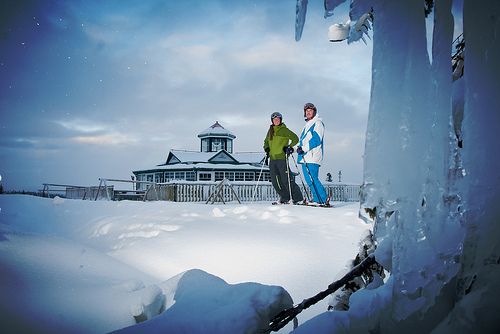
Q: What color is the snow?
A: White.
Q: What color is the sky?
A: Blue.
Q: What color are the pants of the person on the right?
A: Blue.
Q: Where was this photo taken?
A: Winter.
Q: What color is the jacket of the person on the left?
A: Green.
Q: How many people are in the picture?
A: Two.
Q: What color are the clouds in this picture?
A: White.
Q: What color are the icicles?
A: White.